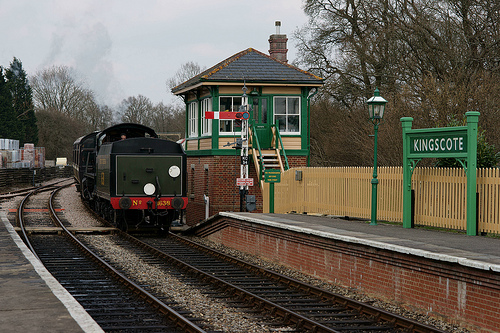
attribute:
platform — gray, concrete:
[170, 209, 499, 331]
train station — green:
[174, 20, 321, 219]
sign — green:
[398, 111, 483, 239]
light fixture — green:
[362, 84, 387, 230]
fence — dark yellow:
[262, 160, 498, 236]